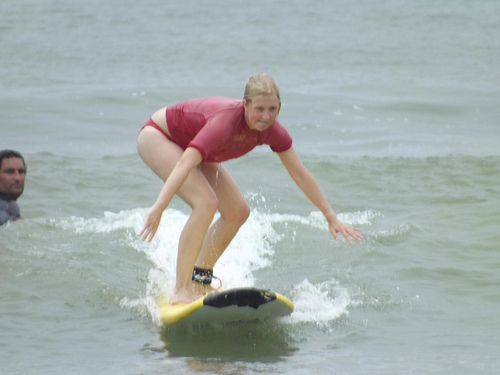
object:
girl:
[135, 73, 364, 308]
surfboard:
[152, 285, 293, 329]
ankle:
[192, 265, 214, 284]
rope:
[207, 274, 224, 293]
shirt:
[164, 97, 292, 165]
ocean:
[1, 1, 496, 374]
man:
[0, 149, 25, 225]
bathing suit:
[137, 115, 174, 142]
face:
[242, 93, 282, 132]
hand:
[139, 209, 161, 243]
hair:
[242, 72, 281, 116]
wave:
[54, 211, 374, 329]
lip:
[257, 120, 269, 124]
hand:
[328, 222, 364, 244]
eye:
[255, 105, 265, 113]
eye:
[268, 105, 277, 113]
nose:
[261, 108, 271, 121]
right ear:
[241, 98, 247, 106]